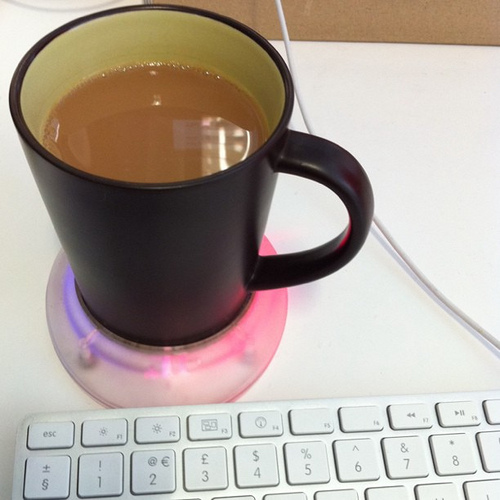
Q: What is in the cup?
A: Coffee.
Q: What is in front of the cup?
A: Keyboard.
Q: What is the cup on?
A: Coaster.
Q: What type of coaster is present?
A: Lighted.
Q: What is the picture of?
A: Desk.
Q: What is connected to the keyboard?
A: Cord.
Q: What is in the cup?
A: Coffee.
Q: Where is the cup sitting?
A: Cup holder.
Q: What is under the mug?
A: Mug warmer.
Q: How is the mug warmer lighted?
A: Led.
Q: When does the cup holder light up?
A: When turned on.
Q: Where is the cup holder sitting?
A: Beside keyboard.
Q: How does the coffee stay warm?
A: Cup holder.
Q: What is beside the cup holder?
A: Keyboard.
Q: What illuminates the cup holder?
A: Led.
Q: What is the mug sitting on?
A: Coaster.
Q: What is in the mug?
A: Coffee.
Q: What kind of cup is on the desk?
A: Coffee cup.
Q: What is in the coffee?
A: Cream.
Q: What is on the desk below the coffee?
A: Keyboard.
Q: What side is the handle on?
A: Right.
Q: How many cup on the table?
A: Just one.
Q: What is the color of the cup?
A: Black.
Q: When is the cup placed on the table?
A: Earlier.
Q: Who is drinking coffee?
A: No one.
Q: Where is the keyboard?
A: In front of the cup.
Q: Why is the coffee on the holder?
A: So it won't spill.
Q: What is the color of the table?
A: White.